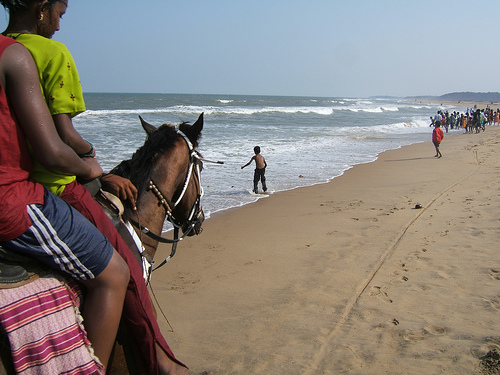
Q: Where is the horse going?
A: Shore line.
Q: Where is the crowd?
A: Further down.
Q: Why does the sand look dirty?
A: Foot traffic.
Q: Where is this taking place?
A: Caribbean.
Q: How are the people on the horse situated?
A: Seated.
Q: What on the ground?
A: Sand.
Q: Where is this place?
A: Beach.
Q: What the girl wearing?
A: Green shirt.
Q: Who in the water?
A: Boy.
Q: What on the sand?
A: Foot prints.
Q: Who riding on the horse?
A: Two people.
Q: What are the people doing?
A: Playing at the beach.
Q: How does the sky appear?
A: Clear and blue.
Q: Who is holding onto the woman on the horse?
A: A man.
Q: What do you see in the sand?
A: A line.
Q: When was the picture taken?
A: Daytime.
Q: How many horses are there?
A: One.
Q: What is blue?
A: Sky.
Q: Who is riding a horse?
A: Two people.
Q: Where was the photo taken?
A: At the beach.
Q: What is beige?
A: Sand.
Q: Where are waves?
A: In the ocean.